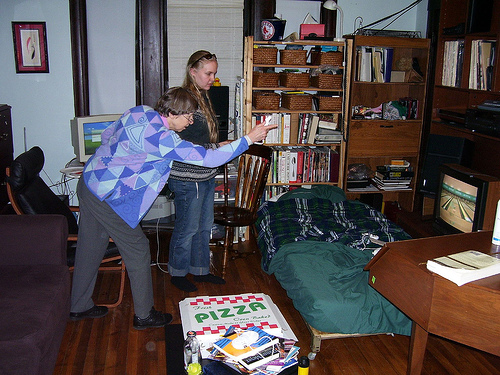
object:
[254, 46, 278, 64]
baskets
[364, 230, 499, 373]
table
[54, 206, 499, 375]
floor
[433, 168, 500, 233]
computer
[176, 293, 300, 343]
box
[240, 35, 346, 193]
bookcase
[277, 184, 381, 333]
cot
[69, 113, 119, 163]
computer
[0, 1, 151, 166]
background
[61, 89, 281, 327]
lady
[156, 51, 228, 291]
lady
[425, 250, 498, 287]
book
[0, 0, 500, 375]
bedroom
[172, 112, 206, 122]
glasses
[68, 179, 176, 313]
pants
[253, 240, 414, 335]
cover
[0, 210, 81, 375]
couch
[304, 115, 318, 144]
books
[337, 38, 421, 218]
shelve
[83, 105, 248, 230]
sweater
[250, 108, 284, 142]
controller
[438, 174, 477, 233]
screen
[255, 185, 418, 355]
bed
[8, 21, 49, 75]
frame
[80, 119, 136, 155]
monitor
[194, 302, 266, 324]
pizza